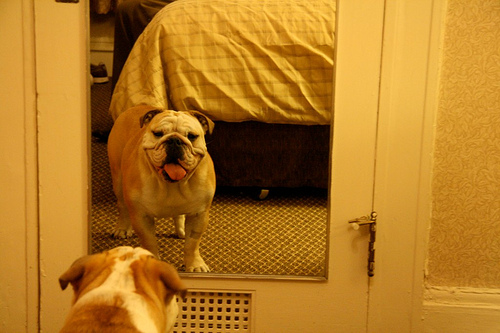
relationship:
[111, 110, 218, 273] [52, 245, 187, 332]
reflection of a dog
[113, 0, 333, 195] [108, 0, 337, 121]
bed with a comforter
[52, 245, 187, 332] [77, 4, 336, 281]
dog looking in mirror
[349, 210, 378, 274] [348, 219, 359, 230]
door hinge with stopper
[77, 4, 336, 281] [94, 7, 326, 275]
mirror reflecting bedroom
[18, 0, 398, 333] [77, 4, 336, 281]
door with mirror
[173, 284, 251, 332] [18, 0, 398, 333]
vent in a door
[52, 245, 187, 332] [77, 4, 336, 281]
dog faces mirror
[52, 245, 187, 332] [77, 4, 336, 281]
dog reflection in mirror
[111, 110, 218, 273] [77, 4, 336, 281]
reflection in mirror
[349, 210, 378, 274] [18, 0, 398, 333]
door hinge on door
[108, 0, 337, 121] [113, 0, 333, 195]
comforter on bed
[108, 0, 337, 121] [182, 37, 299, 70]
comforter has lines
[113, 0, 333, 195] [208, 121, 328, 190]
bed has bottom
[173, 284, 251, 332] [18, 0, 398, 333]
vent on door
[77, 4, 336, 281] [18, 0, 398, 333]
mirror on door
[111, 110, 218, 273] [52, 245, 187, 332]
reflection of dog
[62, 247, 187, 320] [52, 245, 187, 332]
head of dog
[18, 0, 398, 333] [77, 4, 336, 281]
door has mirror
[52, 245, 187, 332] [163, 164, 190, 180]
dog has a tongue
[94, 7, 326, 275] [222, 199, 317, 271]
reflection of carpet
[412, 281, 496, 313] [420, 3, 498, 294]
moulding on wall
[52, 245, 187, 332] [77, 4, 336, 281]
dog stands by mirror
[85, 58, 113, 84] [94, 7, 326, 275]
shoes in reflection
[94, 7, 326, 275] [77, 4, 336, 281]
reflection in mirror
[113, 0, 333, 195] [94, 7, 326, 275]
bed in reflection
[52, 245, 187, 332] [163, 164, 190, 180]
dog has tongue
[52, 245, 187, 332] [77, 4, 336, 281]
dog in mirror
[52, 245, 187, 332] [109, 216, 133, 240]
dog has paws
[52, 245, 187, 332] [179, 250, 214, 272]
dog has paws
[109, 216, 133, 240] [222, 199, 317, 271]
paws on carpet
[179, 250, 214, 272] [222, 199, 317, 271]
paws on carpet